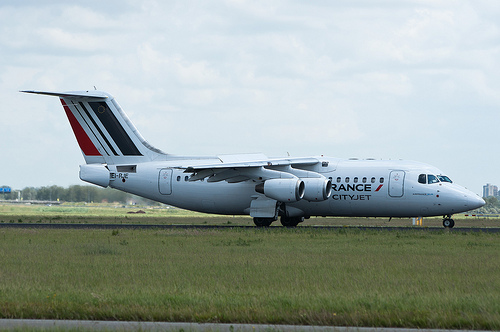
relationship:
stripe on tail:
[90, 100, 142, 153] [22, 90, 165, 202]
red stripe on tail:
[55, 98, 104, 160] [16, 82, 155, 166]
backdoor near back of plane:
[158, 167, 174, 195] [17, 88, 487, 230]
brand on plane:
[331, 184, 372, 201] [17, 88, 487, 230]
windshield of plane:
[417, 171, 453, 184] [15, 79, 495, 239]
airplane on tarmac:
[16, 85, 488, 229] [4, 212, 497, 248]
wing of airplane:
[181, 151, 334, 207] [16, 75, 491, 240]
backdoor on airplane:
[158, 166, 175, 197] [18, 85, 488, 226]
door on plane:
[387, 169, 405, 198] [17, 88, 487, 230]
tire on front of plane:
[442, 217, 454, 227] [17, 88, 487, 230]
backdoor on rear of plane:
[158, 167, 174, 195] [17, 88, 487, 230]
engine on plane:
[295, 176, 334, 204] [17, 88, 487, 230]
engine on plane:
[255, 177, 306, 203] [17, 88, 487, 230]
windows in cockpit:
[414, 168, 457, 187] [407, 168, 482, 210]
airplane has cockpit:
[16, 85, 488, 229] [407, 168, 482, 210]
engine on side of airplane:
[295, 177, 333, 203] [16, 75, 491, 240]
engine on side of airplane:
[264, 174, 308, 204] [16, 75, 491, 240]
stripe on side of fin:
[61, 97, 142, 154] [58, 87, 162, 163]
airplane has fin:
[18, 85, 488, 226] [58, 87, 162, 163]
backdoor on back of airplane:
[158, 167, 174, 195] [16, 75, 491, 240]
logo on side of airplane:
[325, 174, 385, 206] [16, 85, 488, 229]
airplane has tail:
[16, 85, 488, 229] [17, 93, 175, 160]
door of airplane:
[385, 166, 410, 216] [29, 50, 491, 288]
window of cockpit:
[417, 172, 427, 183] [418, 171, 455, 186]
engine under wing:
[255, 177, 306, 203] [179, 139, 313, 213]